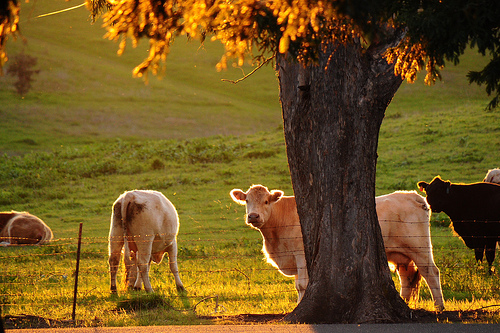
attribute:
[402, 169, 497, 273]
cow — black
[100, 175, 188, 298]
cow — white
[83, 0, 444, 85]
leaves — brown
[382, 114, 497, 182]
grass — green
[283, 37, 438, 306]
trunk — brown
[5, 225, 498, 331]
wire fence — small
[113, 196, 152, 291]
tail — white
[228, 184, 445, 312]
cow — forward facing, white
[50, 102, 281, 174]
grass — green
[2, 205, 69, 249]
cow — brown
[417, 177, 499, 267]
cow — black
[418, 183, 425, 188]
tag — orange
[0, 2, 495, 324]
field — green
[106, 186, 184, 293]
cow — white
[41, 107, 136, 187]
grass — green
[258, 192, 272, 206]
eye — small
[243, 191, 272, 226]
face — white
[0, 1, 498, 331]
grass — green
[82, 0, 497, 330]
tree — large